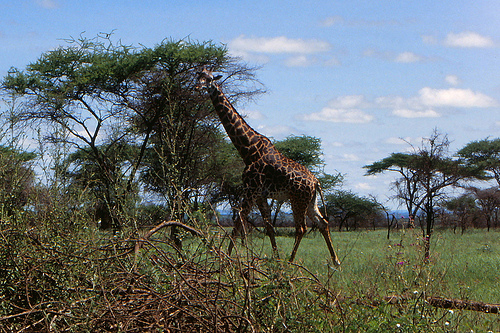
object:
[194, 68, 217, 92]
head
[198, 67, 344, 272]
giraffe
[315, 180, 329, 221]
tail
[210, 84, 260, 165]
neck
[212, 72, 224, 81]
ear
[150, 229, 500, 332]
grass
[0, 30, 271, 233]
tree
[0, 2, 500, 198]
sky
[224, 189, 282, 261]
leg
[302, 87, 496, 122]
clouds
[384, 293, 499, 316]
wood